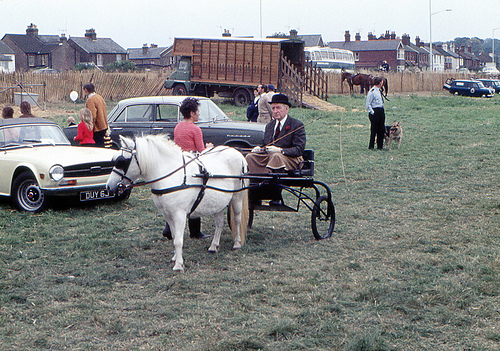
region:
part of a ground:
[384, 239, 439, 295]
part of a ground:
[372, 232, 420, 276]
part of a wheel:
[299, 210, 326, 250]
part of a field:
[348, 247, 403, 307]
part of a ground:
[402, 198, 436, 229]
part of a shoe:
[273, 185, 278, 192]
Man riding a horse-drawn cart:
[103, 92, 339, 273]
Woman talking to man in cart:
[174, 99, 205, 162]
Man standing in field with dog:
[365, 74, 401, 160]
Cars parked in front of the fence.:
[442, 68, 499, 101]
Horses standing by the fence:
[336, 64, 390, 99]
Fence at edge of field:
[0, 66, 499, 101]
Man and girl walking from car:
[72, 82, 116, 143]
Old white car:
[0, 115, 133, 216]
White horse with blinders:
[104, 134, 251, 277]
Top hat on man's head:
[264, 91, 297, 108]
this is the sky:
[99, 9, 181, 33]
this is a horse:
[136, 138, 237, 218]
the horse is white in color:
[139, 144, 169, 167]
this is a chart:
[268, 166, 341, 243]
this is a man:
[255, 89, 300, 164]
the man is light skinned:
[278, 105, 287, 117]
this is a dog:
[382, 113, 414, 158]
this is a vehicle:
[19, 131, 74, 197]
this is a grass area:
[402, 153, 491, 275]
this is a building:
[363, 38, 406, 58]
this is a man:
[358, 72, 388, 145]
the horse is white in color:
[142, 151, 163, 167]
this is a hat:
[271, 92, 292, 102]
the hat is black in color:
[268, 95, 289, 104]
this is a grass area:
[356, 182, 423, 268]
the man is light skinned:
[279, 105, 284, 115]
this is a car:
[7, 110, 77, 190]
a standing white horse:
[98, 138, 256, 282]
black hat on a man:
[263, 93, 298, 114]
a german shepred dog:
[381, 120, 403, 152]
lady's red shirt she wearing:
[70, 123, 95, 146]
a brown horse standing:
[337, 65, 368, 95]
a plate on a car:
[78, 187, 128, 205]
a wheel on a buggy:
[299, 183, 346, 265]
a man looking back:
[348, 69, 390, 142]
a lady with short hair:
[164, 94, 204, 156]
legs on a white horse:
[158, 210, 257, 279]